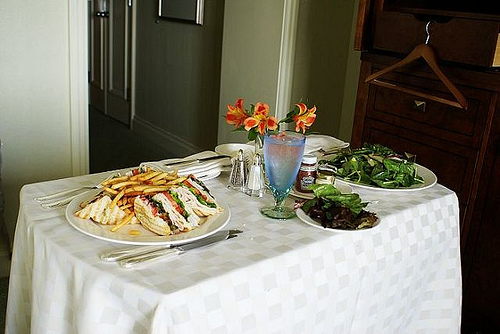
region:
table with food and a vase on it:
[9, 131, 460, 332]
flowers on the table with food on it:
[223, 94, 320, 134]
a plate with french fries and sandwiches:
[64, 166, 231, 244]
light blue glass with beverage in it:
[260, 129, 305, 220]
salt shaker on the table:
[242, 152, 265, 198]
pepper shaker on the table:
[227, 147, 247, 189]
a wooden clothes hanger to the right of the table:
[364, 22, 471, 112]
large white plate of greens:
[327, 145, 439, 190]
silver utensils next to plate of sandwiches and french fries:
[99, 231, 246, 268]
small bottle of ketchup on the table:
[296, 154, 318, 194]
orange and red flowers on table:
[225, 86, 315, 219]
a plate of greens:
[308, 143, 445, 204]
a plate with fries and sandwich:
[66, 130, 233, 267]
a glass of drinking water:
[248, 120, 315, 235]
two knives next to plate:
[102, 225, 254, 276]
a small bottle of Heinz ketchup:
[294, 156, 321, 193]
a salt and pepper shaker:
[226, 148, 262, 210]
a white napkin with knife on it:
[148, 146, 238, 191]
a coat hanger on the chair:
[368, 12, 493, 127]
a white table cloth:
[21, 98, 460, 333]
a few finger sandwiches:
[137, 198, 201, 225]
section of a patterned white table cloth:
[302, 283, 379, 309]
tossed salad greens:
[350, 150, 410, 185]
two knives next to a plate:
[125, 236, 242, 267]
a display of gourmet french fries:
[122, 173, 167, 194]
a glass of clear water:
[263, 131, 301, 221]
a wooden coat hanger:
[366, 18, 475, 107]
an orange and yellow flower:
[244, 101, 277, 136]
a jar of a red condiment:
[298, 155, 314, 188]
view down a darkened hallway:
[86, 1, 216, 140]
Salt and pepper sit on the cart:
[226, 149, 264, 198]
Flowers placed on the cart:
[218, 93, 318, 155]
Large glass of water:
[258, 130, 306, 220]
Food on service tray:
[6, 126, 463, 332]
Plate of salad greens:
[315, 143, 437, 190]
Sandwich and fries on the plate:
[64, 164, 232, 245]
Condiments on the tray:
[288, 150, 355, 200]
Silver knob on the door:
[95, 10, 107, 18]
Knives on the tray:
[99, 229, 244, 266]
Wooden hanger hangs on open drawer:
[363, 20, 468, 111]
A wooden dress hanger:
[364, 20, 469, 112]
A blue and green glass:
[257, 129, 305, 219]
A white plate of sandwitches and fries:
[64, 166, 231, 244]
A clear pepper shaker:
[227, 149, 247, 191]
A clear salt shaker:
[240, 153, 265, 198]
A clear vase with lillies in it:
[220, 97, 317, 190]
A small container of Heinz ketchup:
[294, 154, 317, 193]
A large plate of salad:
[316, 144, 438, 193]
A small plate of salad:
[293, 186, 382, 231]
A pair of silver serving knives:
[97, 226, 241, 267]